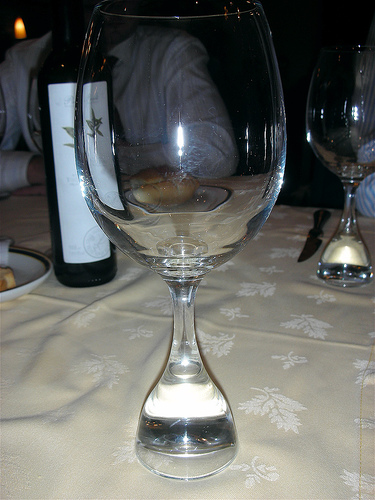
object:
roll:
[131, 176, 198, 207]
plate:
[122, 183, 235, 216]